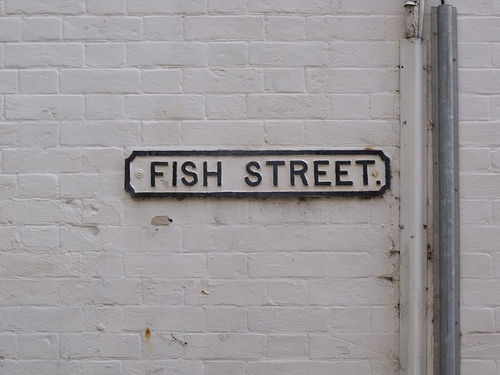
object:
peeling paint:
[83, 224, 100, 235]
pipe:
[399, 31, 430, 373]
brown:
[161, 83, 230, 114]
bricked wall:
[0, 0, 499, 375]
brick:
[19, 14, 65, 44]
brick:
[306, 277, 393, 305]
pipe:
[432, 1, 462, 374]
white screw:
[134, 168, 145, 179]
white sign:
[130, 155, 384, 191]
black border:
[121, 148, 390, 202]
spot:
[141, 324, 154, 341]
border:
[122, 148, 393, 201]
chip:
[150, 215, 173, 226]